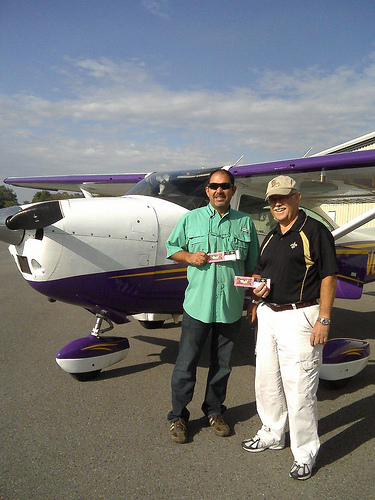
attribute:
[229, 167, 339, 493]
man — older 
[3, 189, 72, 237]
propeller — black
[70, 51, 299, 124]
sky — blue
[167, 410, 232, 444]
tennis shoes — brown 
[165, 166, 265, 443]
man — blue, balding, standing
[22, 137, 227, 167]
cloud — scattered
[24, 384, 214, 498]
road — tarmacked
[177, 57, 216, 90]
wall — tarmacked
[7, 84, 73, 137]
cloud — white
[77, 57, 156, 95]
clouds — white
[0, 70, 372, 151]
clouds — white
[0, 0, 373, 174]
sky — blue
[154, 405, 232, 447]
shoe — man's shoe, brown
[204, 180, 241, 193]
glasses — black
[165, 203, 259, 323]
shirt — green , button-down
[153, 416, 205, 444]
shoe — brown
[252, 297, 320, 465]
pants — white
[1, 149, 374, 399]
plane — white, purple 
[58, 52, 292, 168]
clouds — white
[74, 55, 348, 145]
clouds — white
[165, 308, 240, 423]
jeans — dark 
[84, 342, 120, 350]
marks — Yellow